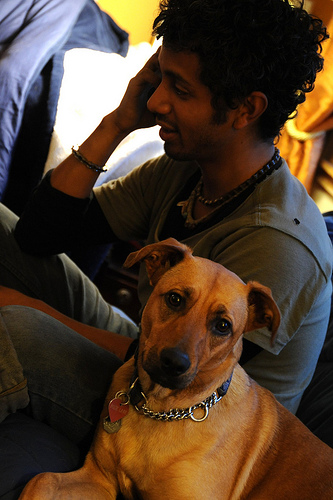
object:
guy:
[1, 0, 333, 499]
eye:
[169, 80, 189, 99]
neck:
[138, 381, 215, 403]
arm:
[0, 122, 188, 299]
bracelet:
[68, 145, 107, 174]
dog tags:
[100, 397, 128, 433]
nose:
[159, 348, 190, 376]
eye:
[165, 287, 185, 312]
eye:
[213, 317, 232, 336]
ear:
[233, 90, 268, 132]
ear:
[240, 280, 282, 348]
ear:
[121, 237, 192, 285]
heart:
[106, 390, 131, 423]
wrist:
[88, 113, 118, 170]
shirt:
[14, 137, 333, 421]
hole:
[292, 216, 301, 224]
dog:
[19, 233, 333, 499]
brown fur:
[275, 438, 305, 469]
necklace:
[190, 151, 280, 206]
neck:
[196, 140, 277, 195]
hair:
[153, 0, 333, 150]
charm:
[106, 396, 127, 421]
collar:
[102, 324, 234, 439]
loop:
[187, 402, 209, 421]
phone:
[138, 66, 161, 113]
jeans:
[1, 201, 145, 500]